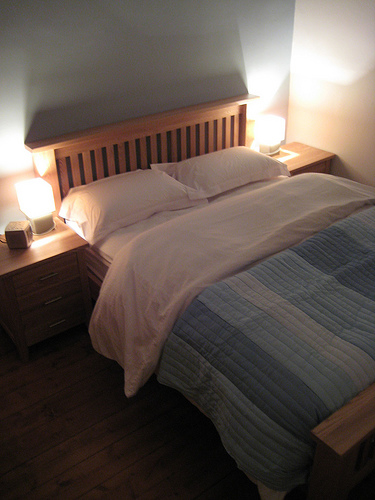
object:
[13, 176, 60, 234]
light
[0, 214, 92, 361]
nightstand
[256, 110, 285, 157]
light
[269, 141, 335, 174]
nightstand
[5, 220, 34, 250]
clock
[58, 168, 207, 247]
pillow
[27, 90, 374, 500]
bed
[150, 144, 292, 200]
pillow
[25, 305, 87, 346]
drawer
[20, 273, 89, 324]
drawer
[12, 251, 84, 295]
drawer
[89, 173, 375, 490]
comforter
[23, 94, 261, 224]
headboard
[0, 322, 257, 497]
floor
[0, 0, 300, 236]
wall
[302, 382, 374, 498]
footboard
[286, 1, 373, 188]
wall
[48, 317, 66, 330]
handle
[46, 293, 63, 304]
handle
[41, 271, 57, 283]
handle